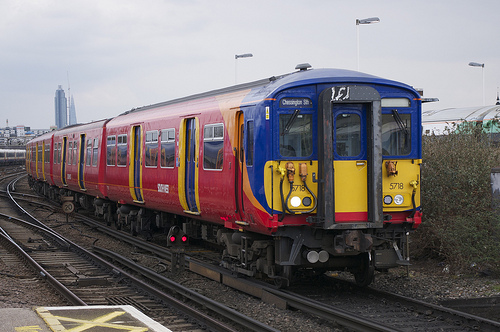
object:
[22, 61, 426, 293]
train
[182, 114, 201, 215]
door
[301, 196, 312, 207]
light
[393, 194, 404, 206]
headlights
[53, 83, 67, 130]
building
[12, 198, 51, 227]
tracks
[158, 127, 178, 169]
windows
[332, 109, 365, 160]
windows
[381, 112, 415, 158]
windows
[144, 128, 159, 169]
windows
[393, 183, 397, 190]
numbers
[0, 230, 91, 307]
train tracks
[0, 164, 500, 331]
ground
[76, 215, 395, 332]
train tracks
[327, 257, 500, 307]
gravel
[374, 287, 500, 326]
train tracks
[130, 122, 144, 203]
door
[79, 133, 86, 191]
door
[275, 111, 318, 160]
front windows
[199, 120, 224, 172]
side windows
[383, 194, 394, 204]
headlights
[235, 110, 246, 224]
front door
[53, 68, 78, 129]
distance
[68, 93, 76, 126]
building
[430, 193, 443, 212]
bushes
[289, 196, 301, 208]
headlight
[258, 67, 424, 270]
train front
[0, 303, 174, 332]
platform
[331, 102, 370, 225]
entrance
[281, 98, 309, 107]
writing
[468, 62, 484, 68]
flag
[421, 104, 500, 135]
structure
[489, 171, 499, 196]
structure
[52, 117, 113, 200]
train car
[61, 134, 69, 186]
side doors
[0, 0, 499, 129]
background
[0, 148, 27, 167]
train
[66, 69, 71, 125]
lightpole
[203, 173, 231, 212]
red